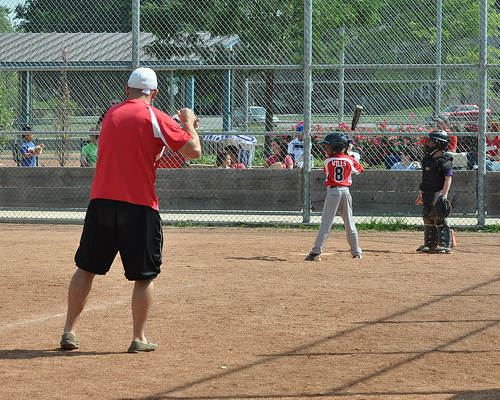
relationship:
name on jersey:
[332, 159, 350, 166] [322, 156, 360, 183]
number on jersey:
[330, 165, 347, 182] [322, 156, 360, 183]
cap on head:
[318, 132, 348, 154] [322, 140, 350, 156]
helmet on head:
[429, 130, 456, 148] [425, 135, 445, 153]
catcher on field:
[416, 127, 455, 254] [2, 217, 486, 399]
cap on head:
[127, 67, 158, 89] [119, 67, 161, 103]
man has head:
[57, 65, 204, 352] [119, 67, 161, 103]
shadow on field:
[7, 347, 115, 360] [2, 217, 486, 399]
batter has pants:
[296, 96, 364, 261] [309, 187, 361, 260]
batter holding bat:
[296, 96, 364, 261] [349, 102, 365, 136]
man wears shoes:
[57, 65, 204, 352] [55, 327, 167, 356]